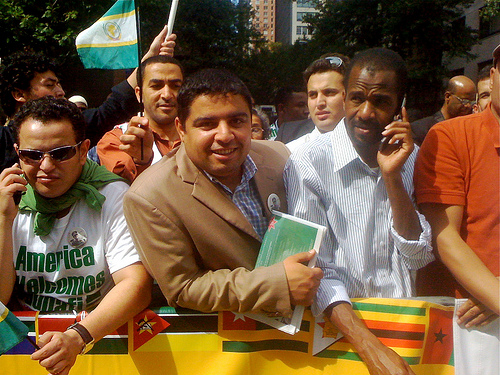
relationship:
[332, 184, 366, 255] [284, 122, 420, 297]
stripes on a shirt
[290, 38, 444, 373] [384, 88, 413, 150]
man holding phone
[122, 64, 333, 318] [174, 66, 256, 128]
man has brown hair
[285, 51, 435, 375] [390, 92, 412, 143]
man talking on cell phone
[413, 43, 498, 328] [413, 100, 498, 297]
man wearing an orange shirt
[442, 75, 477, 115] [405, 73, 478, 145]
head of a man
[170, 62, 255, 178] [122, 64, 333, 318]
head of a man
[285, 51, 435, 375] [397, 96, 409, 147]
man talking on cellphone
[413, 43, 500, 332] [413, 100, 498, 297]
man wearing orange shirt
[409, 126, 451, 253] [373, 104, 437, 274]
shadow on man's arm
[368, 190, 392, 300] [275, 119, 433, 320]
buttons on a shirt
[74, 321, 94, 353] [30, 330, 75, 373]
watch on a hand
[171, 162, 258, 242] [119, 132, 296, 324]
lapel on jacket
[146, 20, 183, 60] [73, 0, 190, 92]
hand holding flag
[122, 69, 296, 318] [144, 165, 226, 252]
man wears jacket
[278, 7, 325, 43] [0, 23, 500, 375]
buildings behind group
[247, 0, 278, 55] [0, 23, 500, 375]
buildings behind group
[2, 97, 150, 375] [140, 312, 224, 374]
man behind fence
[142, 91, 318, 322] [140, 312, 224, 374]
person behind fence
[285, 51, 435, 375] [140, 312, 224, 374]
man behind fence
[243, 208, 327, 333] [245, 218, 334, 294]
hand holding newspaper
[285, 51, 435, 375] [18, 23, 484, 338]
man in group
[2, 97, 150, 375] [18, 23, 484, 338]
man in group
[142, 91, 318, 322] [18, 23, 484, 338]
person in group